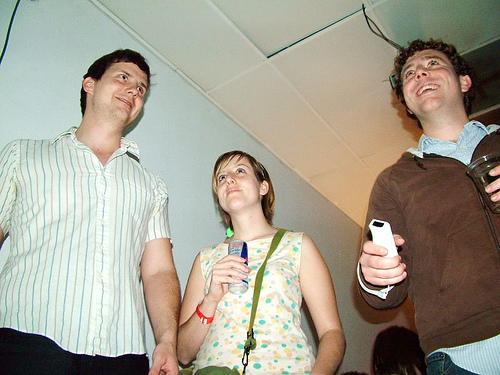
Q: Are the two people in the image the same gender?
A: No, they are both male and female.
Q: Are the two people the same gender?
A: No, they are both male and female.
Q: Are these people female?
A: No, they are both male and female.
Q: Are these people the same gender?
A: No, they are both male and female.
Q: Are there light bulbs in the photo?
A: No, there are no light bulbs.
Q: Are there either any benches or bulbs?
A: No, there are no bulbs or benches.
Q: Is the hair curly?
A: Yes, the hair is curly.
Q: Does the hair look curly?
A: Yes, the hair is curly.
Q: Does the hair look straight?
A: No, the hair is curly.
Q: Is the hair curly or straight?
A: The hair is curly.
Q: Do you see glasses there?
A: No, there are no glasses.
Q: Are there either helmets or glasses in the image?
A: No, there are no glasses or helmets.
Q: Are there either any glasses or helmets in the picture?
A: No, there are no glasses or helmets.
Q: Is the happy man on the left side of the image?
A: Yes, the man is on the left of the image.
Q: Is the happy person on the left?
A: Yes, the man is on the left of the image.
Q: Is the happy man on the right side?
A: No, the man is on the left of the image.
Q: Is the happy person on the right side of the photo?
A: No, the man is on the left of the image.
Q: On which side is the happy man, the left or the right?
A: The man is on the left of the image.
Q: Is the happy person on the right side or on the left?
A: The man is on the left of the image.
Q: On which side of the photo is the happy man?
A: The man is on the left of the image.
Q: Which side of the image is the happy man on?
A: The man is on the left of the image.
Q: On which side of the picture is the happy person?
A: The man is on the left of the image.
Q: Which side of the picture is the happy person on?
A: The man is on the left of the image.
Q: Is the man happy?
A: Yes, the man is happy.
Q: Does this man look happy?
A: Yes, the man is happy.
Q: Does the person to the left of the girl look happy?
A: Yes, the man is happy.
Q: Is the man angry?
A: No, the man is happy.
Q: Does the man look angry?
A: No, the man is happy.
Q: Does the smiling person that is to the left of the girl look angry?
A: No, the man is happy.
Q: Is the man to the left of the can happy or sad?
A: The man is happy.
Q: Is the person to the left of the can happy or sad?
A: The man is happy.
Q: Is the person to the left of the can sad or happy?
A: The man is happy.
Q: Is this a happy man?
A: Yes, this is a happy man.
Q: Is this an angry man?
A: No, this is a happy man.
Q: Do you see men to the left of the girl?
A: Yes, there is a man to the left of the girl.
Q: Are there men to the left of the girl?
A: Yes, there is a man to the left of the girl.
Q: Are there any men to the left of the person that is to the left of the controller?
A: Yes, there is a man to the left of the girl.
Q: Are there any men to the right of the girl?
A: No, the man is to the left of the girl.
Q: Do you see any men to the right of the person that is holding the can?
A: No, the man is to the left of the girl.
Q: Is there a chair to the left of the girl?
A: No, there is a man to the left of the girl.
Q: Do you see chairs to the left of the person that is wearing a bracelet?
A: No, there is a man to the left of the girl.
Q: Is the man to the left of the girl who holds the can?
A: Yes, the man is to the left of the girl.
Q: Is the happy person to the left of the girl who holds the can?
A: Yes, the man is to the left of the girl.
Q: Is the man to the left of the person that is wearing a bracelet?
A: Yes, the man is to the left of the girl.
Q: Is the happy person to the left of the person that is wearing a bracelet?
A: Yes, the man is to the left of the girl.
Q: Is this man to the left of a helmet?
A: No, the man is to the left of the girl.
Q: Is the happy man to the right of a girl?
A: No, the man is to the left of a girl.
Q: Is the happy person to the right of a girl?
A: No, the man is to the left of a girl.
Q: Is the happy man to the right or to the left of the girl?
A: The man is to the left of the girl.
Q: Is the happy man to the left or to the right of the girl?
A: The man is to the left of the girl.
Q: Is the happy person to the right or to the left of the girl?
A: The man is to the left of the girl.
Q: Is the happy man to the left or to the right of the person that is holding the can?
A: The man is to the left of the girl.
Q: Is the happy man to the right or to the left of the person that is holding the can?
A: The man is to the left of the girl.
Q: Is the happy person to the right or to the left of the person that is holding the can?
A: The man is to the left of the girl.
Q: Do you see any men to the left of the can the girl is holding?
A: Yes, there is a man to the left of the can.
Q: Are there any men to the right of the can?
A: No, the man is to the left of the can.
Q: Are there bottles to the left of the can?
A: No, there is a man to the left of the can.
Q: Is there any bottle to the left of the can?
A: No, there is a man to the left of the can.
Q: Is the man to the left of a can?
A: Yes, the man is to the left of a can.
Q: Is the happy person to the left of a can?
A: Yes, the man is to the left of a can.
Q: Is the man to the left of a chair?
A: No, the man is to the left of a can.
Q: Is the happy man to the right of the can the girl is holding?
A: No, the man is to the left of the can.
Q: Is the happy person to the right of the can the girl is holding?
A: No, the man is to the left of the can.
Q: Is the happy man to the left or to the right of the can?
A: The man is to the left of the can.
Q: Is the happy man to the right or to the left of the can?
A: The man is to the left of the can.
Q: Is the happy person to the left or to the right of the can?
A: The man is to the left of the can.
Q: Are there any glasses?
A: No, there are no glasses.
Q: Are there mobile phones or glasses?
A: No, there are no glasses or mobile phones.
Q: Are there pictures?
A: No, there are no pictures.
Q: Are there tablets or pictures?
A: No, there are no pictures or tablets.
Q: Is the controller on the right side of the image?
A: Yes, the controller is on the right of the image.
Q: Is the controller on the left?
A: No, the controller is on the right of the image.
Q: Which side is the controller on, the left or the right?
A: The controller is on the right of the image.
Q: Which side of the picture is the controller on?
A: The controller is on the right of the image.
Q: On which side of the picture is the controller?
A: The controller is on the right of the image.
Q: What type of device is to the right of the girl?
A: The device is a controller.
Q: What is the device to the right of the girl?
A: The device is a controller.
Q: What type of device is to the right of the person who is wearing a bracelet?
A: The device is a controller.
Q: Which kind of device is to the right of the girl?
A: The device is a controller.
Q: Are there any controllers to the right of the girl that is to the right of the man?
A: Yes, there is a controller to the right of the girl.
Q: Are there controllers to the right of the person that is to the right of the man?
A: Yes, there is a controller to the right of the girl.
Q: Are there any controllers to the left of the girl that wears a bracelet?
A: No, the controller is to the right of the girl.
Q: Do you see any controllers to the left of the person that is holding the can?
A: No, the controller is to the right of the girl.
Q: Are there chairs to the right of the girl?
A: No, there is a controller to the right of the girl.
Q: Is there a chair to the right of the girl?
A: No, there is a controller to the right of the girl.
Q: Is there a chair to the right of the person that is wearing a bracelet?
A: No, there is a controller to the right of the girl.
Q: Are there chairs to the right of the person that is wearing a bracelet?
A: No, there is a controller to the right of the girl.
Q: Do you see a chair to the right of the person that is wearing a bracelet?
A: No, there is a controller to the right of the girl.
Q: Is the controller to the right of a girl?
A: Yes, the controller is to the right of a girl.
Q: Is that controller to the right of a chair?
A: No, the controller is to the right of a girl.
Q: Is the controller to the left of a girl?
A: No, the controller is to the right of a girl.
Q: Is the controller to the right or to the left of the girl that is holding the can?
A: The controller is to the right of the girl.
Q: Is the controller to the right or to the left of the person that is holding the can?
A: The controller is to the right of the girl.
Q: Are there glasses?
A: No, there are no glasses.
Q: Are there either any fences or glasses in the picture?
A: No, there are no glasses or fences.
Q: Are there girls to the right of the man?
A: Yes, there is a girl to the right of the man.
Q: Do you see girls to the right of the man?
A: Yes, there is a girl to the right of the man.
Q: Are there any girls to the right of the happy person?
A: Yes, there is a girl to the right of the man.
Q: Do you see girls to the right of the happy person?
A: Yes, there is a girl to the right of the man.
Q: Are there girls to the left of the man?
A: No, the girl is to the right of the man.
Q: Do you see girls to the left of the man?
A: No, the girl is to the right of the man.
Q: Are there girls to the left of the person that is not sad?
A: No, the girl is to the right of the man.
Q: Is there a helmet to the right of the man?
A: No, there is a girl to the right of the man.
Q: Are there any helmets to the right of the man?
A: No, there is a girl to the right of the man.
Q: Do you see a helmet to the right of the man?
A: No, there is a girl to the right of the man.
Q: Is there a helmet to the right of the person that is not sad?
A: No, there is a girl to the right of the man.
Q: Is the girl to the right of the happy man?
A: Yes, the girl is to the right of the man.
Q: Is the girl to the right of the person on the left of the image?
A: Yes, the girl is to the right of the man.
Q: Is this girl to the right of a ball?
A: No, the girl is to the right of the man.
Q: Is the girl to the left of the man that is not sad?
A: No, the girl is to the right of the man.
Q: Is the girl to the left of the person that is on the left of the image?
A: No, the girl is to the right of the man.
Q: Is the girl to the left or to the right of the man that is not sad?
A: The girl is to the right of the man.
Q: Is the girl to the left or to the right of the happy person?
A: The girl is to the right of the man.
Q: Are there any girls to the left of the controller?
A: Yes, there is a girl to the left of the controller.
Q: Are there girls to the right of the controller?
A: No, the girl is to the left of the controller.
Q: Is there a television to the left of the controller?
A: No, there is a girl to the left of the controller.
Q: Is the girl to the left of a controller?
A: Yes, the girl is to the left of a controller.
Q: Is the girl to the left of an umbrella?
A: No, the girl is to the left of a controller.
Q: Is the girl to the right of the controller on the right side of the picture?
A: No, the girl is to the left of the controller.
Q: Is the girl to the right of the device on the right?
A: No, the girl is to the left of the controller.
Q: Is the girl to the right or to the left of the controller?
A: The girl is to the left of the controller.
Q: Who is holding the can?
A: The girl is holding the can.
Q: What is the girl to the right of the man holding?
A: The girl is holding the can.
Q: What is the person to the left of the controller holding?
A: The girl is holding the can.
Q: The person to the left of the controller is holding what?
A: The girl is holding the can.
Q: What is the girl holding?
A: The girl is holding the can.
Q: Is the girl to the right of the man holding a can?
A: Yes, the girl is holding a can.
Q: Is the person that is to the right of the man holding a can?
A: Yes, the girl is holding a can.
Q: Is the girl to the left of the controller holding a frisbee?
A: No, the girl is holding a can.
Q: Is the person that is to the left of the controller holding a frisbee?
A: No, the girl is holding a can.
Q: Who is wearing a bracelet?
A: The girl is wearing a bracelet.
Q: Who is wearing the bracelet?
A: The girl is wearing a bracelet.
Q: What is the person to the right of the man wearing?
A: The girl is wearing a bracelet.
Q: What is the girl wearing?
A: The girl is wearing a bracelet.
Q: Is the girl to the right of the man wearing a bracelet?
A: Yes, the girl is wearing a bracelet.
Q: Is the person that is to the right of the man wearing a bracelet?
A: Yes, the girl is wearing a bracelet.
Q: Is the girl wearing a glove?
A: No, the girl is wearing a bracelet.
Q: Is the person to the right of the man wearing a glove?
A: No, the girl is wearing a bracelet.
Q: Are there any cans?
A: Yes, there is a can.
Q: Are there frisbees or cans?
A: Yes, there is a can.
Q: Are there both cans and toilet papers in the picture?
A: No, there is a can but no toilet papers.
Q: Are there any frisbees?
A: No, there are no frisbees.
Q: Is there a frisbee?
A: No, there are no frisbees.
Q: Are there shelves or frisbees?
A: No, there are no frisbees or shelves.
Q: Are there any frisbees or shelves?
A: No, there are no frisbees or shelves.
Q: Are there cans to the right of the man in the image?
A: Yes, there is a can to the right of the man.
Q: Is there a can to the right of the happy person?
A: Yes, there is a can to the right of the man.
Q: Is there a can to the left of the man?
A: No, the can is to the right of the man.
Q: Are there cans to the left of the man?
A: No, the can is to the right of the man.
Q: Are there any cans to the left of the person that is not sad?
A: No, the can is to the right of the man.